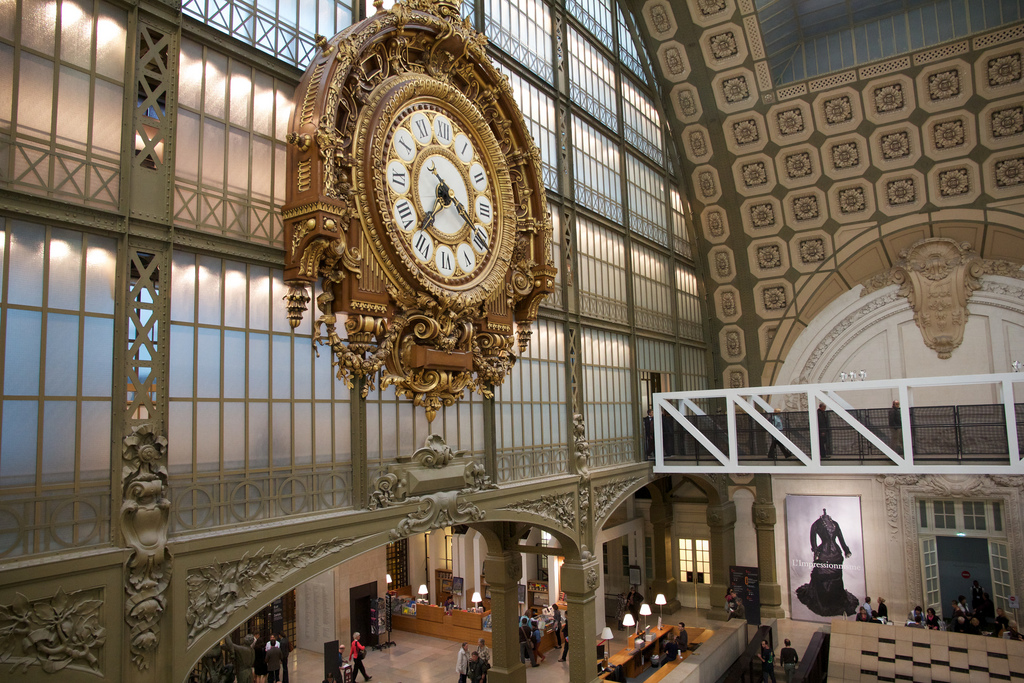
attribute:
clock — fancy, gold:
[285, 13, 562, 413]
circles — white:
[382, 113, 422, 250]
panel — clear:
[138, 234, 635, 503]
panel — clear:
[58, 13, 635, 493]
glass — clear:
[43, 35, 218, 310]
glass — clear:
[540, 70, 668, 325]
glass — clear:
[134, 281, 353, 495]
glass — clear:
[512, 323, 616, 503]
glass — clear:
[190, 288, 348, 567]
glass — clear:
[531, 368, 644, 572]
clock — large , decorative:
[246, 39, 726, 428]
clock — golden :
[244, 139, 804, 494]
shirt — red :
[337, 633, 392, 679]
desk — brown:
[393, 562, 540, 677]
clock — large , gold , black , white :
[278, 35, 596, 394]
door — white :
[909, 489, 990, 641]